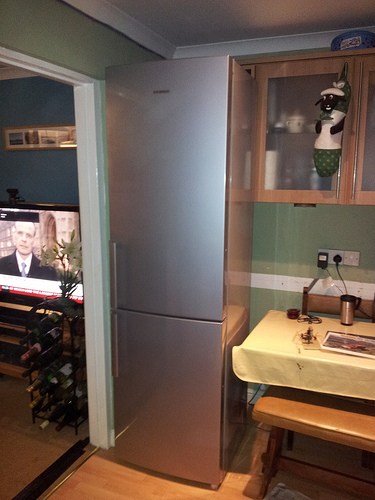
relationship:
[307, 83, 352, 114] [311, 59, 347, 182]
sheep on oven mitt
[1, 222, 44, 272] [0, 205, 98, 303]
man on tv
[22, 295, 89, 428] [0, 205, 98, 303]
wine rack near television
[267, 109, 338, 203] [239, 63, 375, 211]
dishes inside cupboard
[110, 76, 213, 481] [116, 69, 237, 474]
doors on fridge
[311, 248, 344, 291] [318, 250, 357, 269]
cords inserted in outlet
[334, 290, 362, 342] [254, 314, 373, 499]
mug sits on table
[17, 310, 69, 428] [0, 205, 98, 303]
wine bottles near television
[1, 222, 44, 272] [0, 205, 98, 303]
man on television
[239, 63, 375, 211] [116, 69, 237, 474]
cupboard near fridge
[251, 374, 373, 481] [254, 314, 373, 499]
bench near table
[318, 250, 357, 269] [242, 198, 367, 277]
outlet part of wall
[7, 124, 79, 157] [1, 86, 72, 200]
photos hung on wall